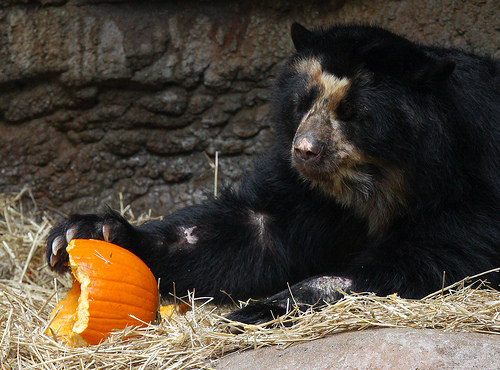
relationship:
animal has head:
[43, 19, 498, 334] [276, 20, 458, 213]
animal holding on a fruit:
[43, 19, 498, 334] [44, 237, 164, 348]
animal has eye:
[43, 19, 498, 334] [337, 103, 357, 120]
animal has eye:
[43, 19, 498, 334] [288, 101, 303, 117]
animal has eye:
[43, 19, 498, 334] [296, 88, 316, 111]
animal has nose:
[43, 19, 498, 334] [284, 139, 326, 173]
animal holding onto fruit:
[43, 19, 498, 334] [44, 237, 164, 348]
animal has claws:
[43, 19, 498, 334] [42, 219, 106, 264]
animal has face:
[43, 19, 498, 334] [281, 57, 401, 189]